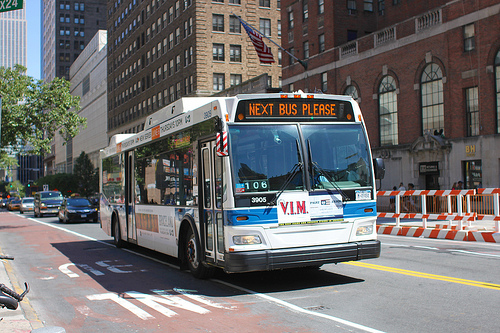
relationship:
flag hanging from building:
[238, 17, 276, 64] [277, 0, 499, 213]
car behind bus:
[52, 192, 97, 224] [93, 84, 384, 287]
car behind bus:
[17, 191, 32, 213] [93, 84, 384, 287]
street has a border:
[2, 205, 499, 332] [378, 195, 494, 215]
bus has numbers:
[93, 84, 384, 287] [242, 177, 269, 194]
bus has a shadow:
[93, 84, 384, 287] [48, 232, 366, 297]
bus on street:
[93, 84, 384, 287] [2, 205, 499, 332]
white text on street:
[62, 260, 234, 318] [2, 205, 499, 332]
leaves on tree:
[0, 83, 19, 133] [0, 62, 88, 193]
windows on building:
[135, 24, 215, 66] [168, 12, 224, 80]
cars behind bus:
[4, 183, 101, 225] [91, 92, 383, 275]